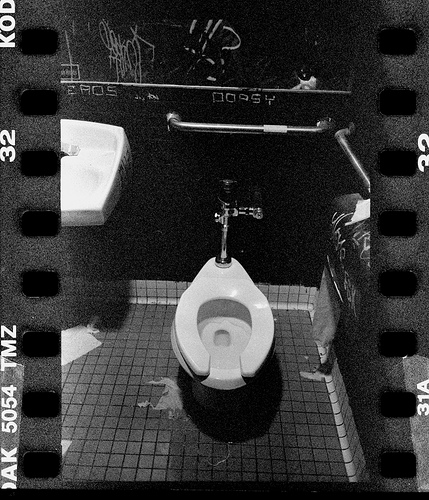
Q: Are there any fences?
A: No, there are no fences.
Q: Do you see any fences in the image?
A: No, there are no fences.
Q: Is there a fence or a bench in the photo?
A: No, there are no fences or benches.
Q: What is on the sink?
A: The graffiti is on the sink.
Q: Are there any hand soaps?
A: No, there are no hand soaps.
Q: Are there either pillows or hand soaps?
A: No, there are no hand soaps or pillows.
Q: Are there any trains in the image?
A: No, there are no trains.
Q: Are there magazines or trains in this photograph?
A: No, there are no trains or magazines.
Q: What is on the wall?
A: The graffiti is on the wall.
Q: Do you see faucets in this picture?
A: No, there are no faucets.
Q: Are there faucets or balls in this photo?
A: No, there are no faucets or balls.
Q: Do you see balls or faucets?
A: No, there are no faucets or balls.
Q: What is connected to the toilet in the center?
A: The pipe is connected to the toilet.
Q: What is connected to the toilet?
A: The pipe is connected to the toilet.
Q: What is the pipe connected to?
A: The pipe is connected to the toilet.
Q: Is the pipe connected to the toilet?
A: Yes, the pipe is connected to the toilet.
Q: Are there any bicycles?
A: No, there are no bicycles.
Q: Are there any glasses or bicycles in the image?
A: No, there are no bicycles or glasses.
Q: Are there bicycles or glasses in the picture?
A: No, there are no bicycles or glasses.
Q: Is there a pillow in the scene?
A: No, there are no pillows.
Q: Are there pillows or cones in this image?
A: No, there are no pillows or cones.